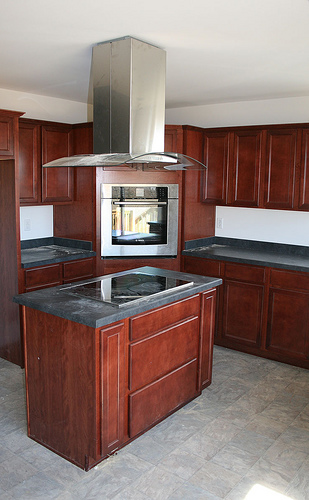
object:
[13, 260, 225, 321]
cooking surface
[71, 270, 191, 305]
range top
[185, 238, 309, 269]
counter space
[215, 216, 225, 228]
outlet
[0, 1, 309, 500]
kitchen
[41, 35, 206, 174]
hood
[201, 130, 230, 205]
cabinets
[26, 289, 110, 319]
dust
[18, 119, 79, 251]
wall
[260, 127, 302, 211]
cabinet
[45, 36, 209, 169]
vent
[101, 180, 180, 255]
oven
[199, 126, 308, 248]
wall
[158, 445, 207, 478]
tile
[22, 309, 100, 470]
wood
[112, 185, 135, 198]
buttons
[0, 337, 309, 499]
tile floor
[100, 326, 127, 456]
door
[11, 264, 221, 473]
island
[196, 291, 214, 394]
cupboard door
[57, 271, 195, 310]
cook top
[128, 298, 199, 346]
top drawer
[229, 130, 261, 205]
cupboard door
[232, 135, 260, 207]
cabinets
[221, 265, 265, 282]
drawer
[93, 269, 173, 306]
stove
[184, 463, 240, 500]
floor tiles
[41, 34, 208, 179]
chimney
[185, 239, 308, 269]
counter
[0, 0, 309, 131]
ceiling